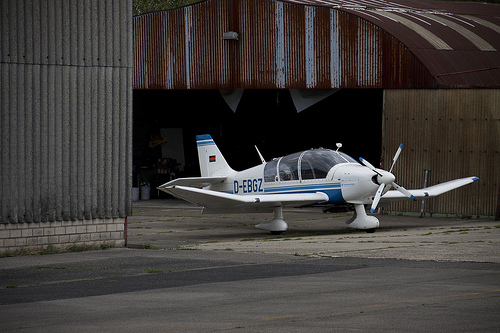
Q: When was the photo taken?
A: Daytime.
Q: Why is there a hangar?
A: To store the airplane.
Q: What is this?
A: An airplane.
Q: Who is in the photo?
A: Nobody.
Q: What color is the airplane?
A: White.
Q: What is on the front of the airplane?
A: A propeller.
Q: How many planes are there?
A: One.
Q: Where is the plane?
A: Near the hangar.